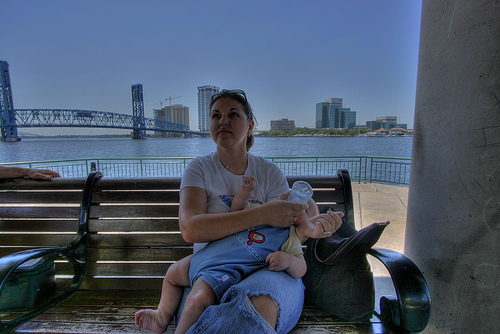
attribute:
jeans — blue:
[178, 265, 304, 331]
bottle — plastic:
[288, 181, 316, 202]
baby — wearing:
[132, 184, 383, 302]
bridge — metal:
[3, 49, 210, 145]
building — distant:
[311, 93, 358, 133]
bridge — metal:
[29, 77, 160, 140]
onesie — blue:
[185, 214, 302, 285]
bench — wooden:
[0, 180, 400, 305]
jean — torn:
[244, 293, 291, 324]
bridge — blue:
[0, 59, 209, 139]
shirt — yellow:
[280, 226, 305, 254]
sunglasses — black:
[210, 85, 252, 105]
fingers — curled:
[301, 209, 345, 238]